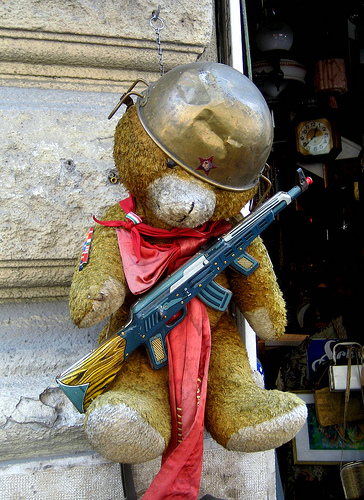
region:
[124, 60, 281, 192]
Battered bowl on head of bear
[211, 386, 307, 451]
Foot of stuffed bear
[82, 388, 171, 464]
Foot of stuffed bear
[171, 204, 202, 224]
Nosr of stuffed bear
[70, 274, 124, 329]
Paw of stuffed bear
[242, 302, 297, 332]
Paw of stuffed bear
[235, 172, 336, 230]
Barrel of toy rifle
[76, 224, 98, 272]
Battle award ribbons on stuffed bear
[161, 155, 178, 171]
Eye of stuffed bear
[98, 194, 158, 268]
Part of bear's red scarf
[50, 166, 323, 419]
Stuffed bear with toy gun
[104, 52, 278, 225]
Metal pot used as helmet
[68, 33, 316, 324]
Stuffed bear with red scarf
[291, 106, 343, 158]
White and brown analog clock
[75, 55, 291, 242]
stuffed bear wearing pot for helmet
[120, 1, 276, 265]
stuffed bear hanging from chain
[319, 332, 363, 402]
White purse with handle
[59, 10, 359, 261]
stuffed bear hanging next to store window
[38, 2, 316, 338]
Stuffed bear hanging from brick wall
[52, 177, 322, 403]
Toy gun on bear with red sash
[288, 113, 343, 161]
An old-looking wooden clock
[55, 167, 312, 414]
A toy rifle with a wooden-looking butt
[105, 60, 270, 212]
AN old pot being used as a helmet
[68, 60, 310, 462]
A teddy bear dressed as a soldier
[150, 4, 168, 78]
Part of a chain holding a toy to the wall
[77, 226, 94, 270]
A military insignia on the side of a teddy bear arm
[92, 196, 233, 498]
A red scarf on a teddy bear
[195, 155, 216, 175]
A red star painted on an old pot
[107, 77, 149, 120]
The side handle of an old pot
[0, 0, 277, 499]
A gray stone wall with cracks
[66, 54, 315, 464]
someone has dressed this teddy bear up as a soldier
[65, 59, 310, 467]
this teddy bear looks old and dirty and well loved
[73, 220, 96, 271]
this teddy bear has been pinned with military ribbons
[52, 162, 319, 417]
this teddy bear is armed with a toy rifle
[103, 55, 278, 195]
this teddy bear is wearing a makeshift military helmet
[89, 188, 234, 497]
this teddy bear is wearing a worn red bow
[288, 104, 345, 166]
the clock inside reads 12:39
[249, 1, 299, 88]
there is a wall sconce lamp inside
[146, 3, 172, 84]
the teddy bear hangs on the wall by a metal chain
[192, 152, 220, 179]
there is some sort of insignia on teddy bear's makeshift helmet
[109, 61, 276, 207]
metal pan with two handles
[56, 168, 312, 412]
toy blue machine gun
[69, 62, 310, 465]
red scarf on teddy bear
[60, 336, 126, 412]
wood pattern on gun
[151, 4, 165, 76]
metal chain on hook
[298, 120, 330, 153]
clock with black hands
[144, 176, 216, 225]
white snout on bear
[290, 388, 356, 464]
framed picture with mat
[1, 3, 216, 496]
stone wall of building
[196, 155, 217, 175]
star on metal pan